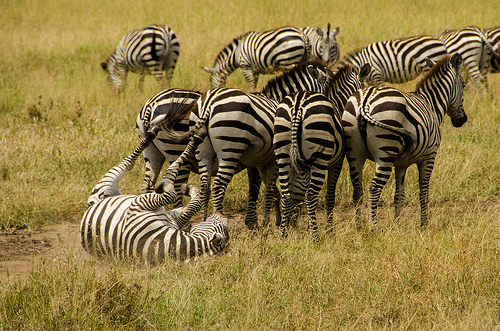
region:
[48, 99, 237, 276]
zebra falling over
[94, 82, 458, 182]
four zebra butts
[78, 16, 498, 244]
a herd a zebra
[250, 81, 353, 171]
the black and white stripes on the zebra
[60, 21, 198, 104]
the zebra grazing in the background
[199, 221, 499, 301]
the grass of the Safari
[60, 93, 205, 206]
the zebra's tail whipping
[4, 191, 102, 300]
dirt in between the grass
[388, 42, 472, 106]
the mane of the zebra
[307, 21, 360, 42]
perked up ears on the zebra's head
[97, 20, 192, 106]
the farthest zebra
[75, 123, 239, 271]
zebra lying on the grass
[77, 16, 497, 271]
a herd of zebras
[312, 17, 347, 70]
the only face of a zebra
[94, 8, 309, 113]
two zebras eating the grass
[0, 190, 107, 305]
the ground without grass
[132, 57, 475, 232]
four zebras together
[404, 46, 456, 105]
tuft of the zebra on the right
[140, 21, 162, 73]
tail of the farthest zebra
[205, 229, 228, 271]
ears of the zebra in the ground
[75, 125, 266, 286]
zebra is on the ground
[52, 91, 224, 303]
the zebra is fooling around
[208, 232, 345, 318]
the grass is green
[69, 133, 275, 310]
the zebra is stripes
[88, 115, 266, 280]
the zebra is black and white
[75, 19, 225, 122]
the zebra is eating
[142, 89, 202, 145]
the zebra's tail is black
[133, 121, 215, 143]
zebra's hooves are black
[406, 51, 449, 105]
zebra's mane is brown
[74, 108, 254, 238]
the zebra has four legs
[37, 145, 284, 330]
the zebra is laying down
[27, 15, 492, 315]
11 zebras are shown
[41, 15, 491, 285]
the zebras have black and white stripes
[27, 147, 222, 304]
the zebra is laying in the dirt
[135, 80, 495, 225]
the zebras are standing next to each other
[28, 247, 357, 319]
the grass is green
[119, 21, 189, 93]
the zebra's tail is black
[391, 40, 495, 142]
the zebra has hair on its neck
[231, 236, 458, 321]
the grass is dry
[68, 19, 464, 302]
many zebras in grass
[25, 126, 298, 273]
one zebra laying on ground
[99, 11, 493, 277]
four zebras lined up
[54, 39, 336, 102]
two zebras eating in grass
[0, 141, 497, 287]
dirt path in photo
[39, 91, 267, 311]
one zebra kicking two others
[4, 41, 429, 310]
green grass in photo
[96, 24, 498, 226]
herd of zebras in photo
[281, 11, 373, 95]
one zebra facing opposite of others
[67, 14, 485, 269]
four zebras standing in line